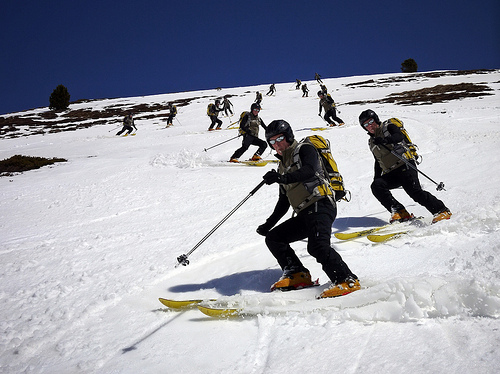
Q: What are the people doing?
A: Skiing.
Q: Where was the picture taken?
A: A ski slope.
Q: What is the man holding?
A: Ski poles.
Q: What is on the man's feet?
A: Skis.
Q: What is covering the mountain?
A: Snow.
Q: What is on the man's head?
A: Ski helmet.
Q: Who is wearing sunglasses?
A: The skier.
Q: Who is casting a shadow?
A: The skier.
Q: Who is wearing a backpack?
A: The skier.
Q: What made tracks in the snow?
A: Skis.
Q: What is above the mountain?
A: Blue sky.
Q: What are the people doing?
A: Skiing.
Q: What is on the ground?
A: Snow.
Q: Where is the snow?
A: On the hill.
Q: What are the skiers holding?
A: Poles.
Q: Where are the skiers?
A: On a hill.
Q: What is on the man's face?
A: Goggles.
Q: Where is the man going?
A: Down the hill.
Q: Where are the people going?
A: Downhill.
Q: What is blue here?
A: The sky.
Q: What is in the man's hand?
A: A ski pole.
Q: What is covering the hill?
A: Snow.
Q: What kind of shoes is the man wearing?
A: Ski shoes.